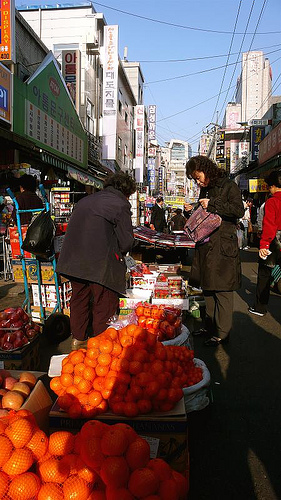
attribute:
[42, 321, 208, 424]
oranges — pile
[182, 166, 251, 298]
coat — long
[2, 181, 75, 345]
cart — blue, metal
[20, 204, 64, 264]
bag — black, plastic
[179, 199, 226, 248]
purse — purple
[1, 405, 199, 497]
bag — mesh, oranges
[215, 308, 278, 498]
shadow — person's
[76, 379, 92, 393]
orange — for sale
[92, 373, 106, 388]
orange — for sale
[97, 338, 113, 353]
orange — for sale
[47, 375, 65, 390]
orange — for sale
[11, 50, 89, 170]
sign — advertising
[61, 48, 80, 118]
sign — advertising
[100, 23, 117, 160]
sign — advertising, not English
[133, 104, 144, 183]
sign — advertising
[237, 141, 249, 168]
sign — advertising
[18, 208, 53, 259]
bag — black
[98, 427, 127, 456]
orange — for sale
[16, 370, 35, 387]
apple — red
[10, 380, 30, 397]
apple — red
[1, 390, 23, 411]
apple — red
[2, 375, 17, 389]
apple — red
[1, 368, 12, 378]
apple — red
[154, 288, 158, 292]
strawberry — red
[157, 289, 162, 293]
strawberry — red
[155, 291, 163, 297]
strawberry — red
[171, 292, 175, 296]
strawberry — red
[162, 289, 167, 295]
strawberry — red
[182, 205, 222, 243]
purse — purple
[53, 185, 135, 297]
jacket — blue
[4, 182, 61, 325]
hand dolly — blue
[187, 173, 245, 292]
coat — black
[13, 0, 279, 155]
sky — light blue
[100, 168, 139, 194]
hair — short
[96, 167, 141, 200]
hair — brown